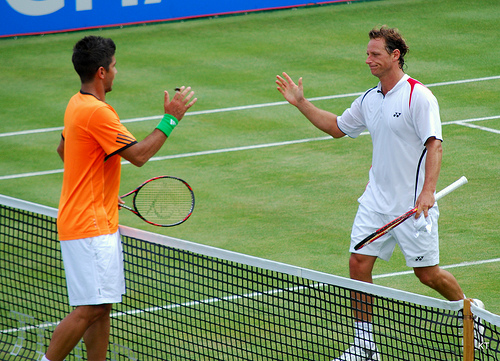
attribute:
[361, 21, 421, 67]
blonde hair — blond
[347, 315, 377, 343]
sock — white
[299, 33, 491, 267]
man — wearing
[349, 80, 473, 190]
shirt — white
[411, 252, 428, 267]
logo — black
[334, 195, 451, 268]
shorts — white